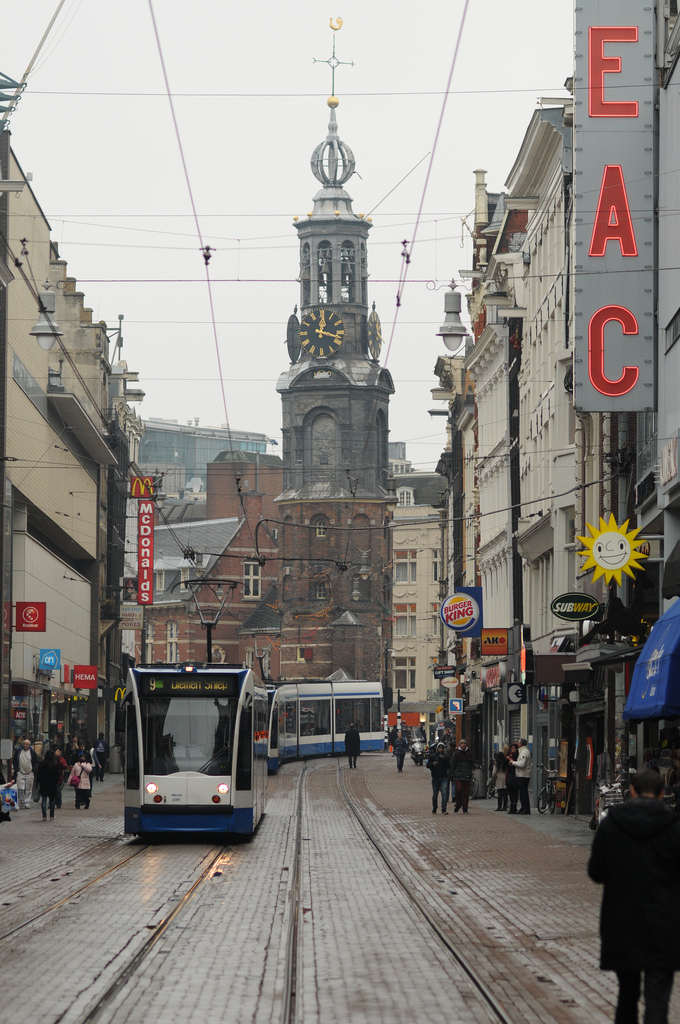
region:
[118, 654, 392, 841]
white and blue train on street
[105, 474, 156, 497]
red and yellow mcdonalds sign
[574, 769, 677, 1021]
man in black coat walking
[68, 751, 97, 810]
child in pink coat holding bag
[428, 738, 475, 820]
man and woman walking on street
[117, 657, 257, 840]
blue and white train with headlights on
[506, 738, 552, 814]
man in white coat standing in front of store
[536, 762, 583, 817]
bike parked in front of store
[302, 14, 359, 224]
gold and silver steeple on top of building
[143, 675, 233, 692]
Digital board that says destination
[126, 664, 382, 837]
Blue and white train on the tracks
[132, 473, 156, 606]
McDonald's sign attached to the side of a building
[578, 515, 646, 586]
Yellow and white sunshine sign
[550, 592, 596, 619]
Small subway sign attached to building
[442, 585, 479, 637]
Burger King sign attached to building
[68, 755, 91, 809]
Woman wearing pink jacket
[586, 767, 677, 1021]
Person in black jacket walking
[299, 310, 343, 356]
Large clock on a tower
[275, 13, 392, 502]
Tall clock tower building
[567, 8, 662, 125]
the letter e on sign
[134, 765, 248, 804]
headlights on a train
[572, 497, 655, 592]
a sun shaped sign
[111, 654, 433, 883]
a blue and white train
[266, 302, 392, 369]
three clocks on a building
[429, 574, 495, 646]
a burger king sign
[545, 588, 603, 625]
a subway sign on building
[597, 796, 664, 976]
a man wearing a black coat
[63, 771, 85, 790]
a woman carrying a pink bag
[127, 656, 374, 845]
a blue and silver train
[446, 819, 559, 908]
a brick walkway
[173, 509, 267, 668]
a red brick building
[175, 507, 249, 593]
a building with a shingled roof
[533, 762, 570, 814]
a bicycle leaning against a building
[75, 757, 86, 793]
a woman wearing a pink coat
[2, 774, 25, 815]
a blue and white plastic bag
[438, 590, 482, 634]
blue Burger King sign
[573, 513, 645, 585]
Yellow sign with smiling sun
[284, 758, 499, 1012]
streetcar tracks in road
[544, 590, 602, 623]
subway sign with yellow and white letters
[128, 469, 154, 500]
mcdonald's golden arches symbol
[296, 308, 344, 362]
black clock on tower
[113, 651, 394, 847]
white and blue street car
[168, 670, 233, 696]
destination sign on streetcar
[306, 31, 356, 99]
grey cross on top of building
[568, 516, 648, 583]
an outdoor signage of a sun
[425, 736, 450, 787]
a person wearing thick jacket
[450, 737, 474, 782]
a person wearing thick jacket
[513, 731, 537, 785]
a person wearing thick jacket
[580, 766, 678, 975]
a person wearing thick jacket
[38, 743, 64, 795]
a person wearing thick jacket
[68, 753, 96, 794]
a person wearing thick jacket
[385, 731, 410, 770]
a person wearing thick jacket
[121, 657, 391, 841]
large blue and white train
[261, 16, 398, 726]
large clock tower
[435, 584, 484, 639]
blue red and white burger king sign hanging on wall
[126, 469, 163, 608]
large red yellow and white Mc donald's signboard hanging on the wall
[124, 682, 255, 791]
dark windshield of train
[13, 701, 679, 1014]
a bunch of people standing in sidewalk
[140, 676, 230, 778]
a window on a train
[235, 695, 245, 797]
a window on a bus